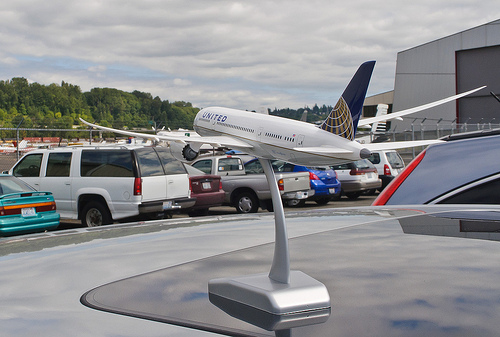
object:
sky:
[8, 4, 478, 94]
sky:
[15, 6, 444, 93]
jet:
[76, 60, 446, 168]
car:
[328, 158, 381, 201]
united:
[202, 111, 229, 122]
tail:
[315, 60, 375, 141]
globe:
[320, 96, 355, 142]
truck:
[190, 154, 310, 213]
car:
[0, 203, 500, 337]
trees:
[6, 84, 168, 128]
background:
[1, 3, 459, 189]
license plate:
[329, 188, 335, 194]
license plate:
[20, 208, 36, 218]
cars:
[0, 146, 196, 228]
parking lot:
[0, 139, 500, 261]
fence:
[0, 118, 165, 162]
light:
[133, 177, 141, 201]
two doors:
[133, 146, 193, 204]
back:
[0, 173, 60, 236]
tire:
[287, 199, 306, 207]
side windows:
[270, 161, 292, 172]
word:
[202, 111, 254, 133]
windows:
[216, 122, 256, 133]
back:
[278, 160, 341, 208]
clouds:
[141, 14, 242, 42]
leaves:
[30, 95, 79, 119]